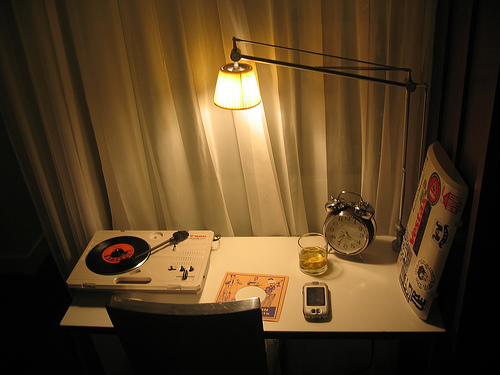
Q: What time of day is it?
A: Night time.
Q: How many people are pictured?
A: No one.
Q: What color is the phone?
A: White.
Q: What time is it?
A: 7:28.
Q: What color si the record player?
A: White.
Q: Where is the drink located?
A: In front of clock.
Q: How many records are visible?
A: One.